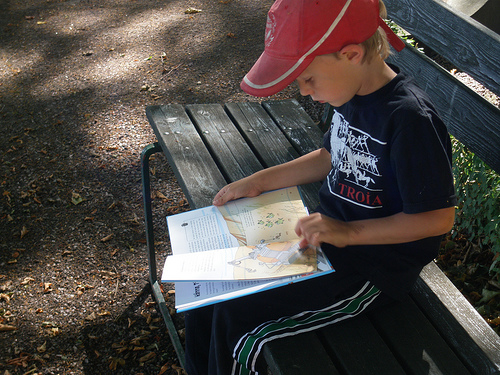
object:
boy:
[181, 1, 458, 375]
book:
[158, 185, 335, 316]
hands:
[210, 173, 344, 248]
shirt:
[305, 63, 459, 299]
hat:
[239, 2, 405, 98]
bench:
[140, 1, 500, 374]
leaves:
[13, 132, 121, 320]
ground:
[0, 1, 340, 374]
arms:
[211, 128, 458, 250]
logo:
[322, 109, 390, 211]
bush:
[436, 131, 498, 339]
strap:
[371, 15, 405, 54]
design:
[210, 208, 304, 253]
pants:
[180, 258, 380, 375]